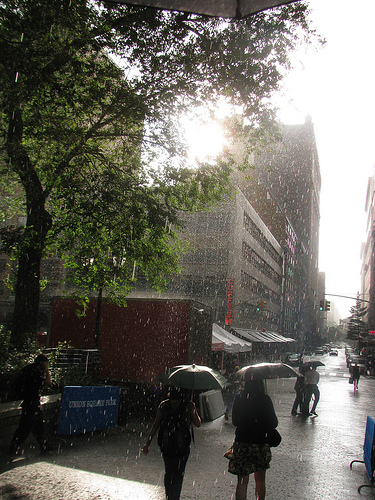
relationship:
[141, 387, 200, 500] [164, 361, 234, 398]
person has umbrella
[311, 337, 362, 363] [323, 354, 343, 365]
parked cars on street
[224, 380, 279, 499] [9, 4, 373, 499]
people walking in rain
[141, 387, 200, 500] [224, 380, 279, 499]
person walking in people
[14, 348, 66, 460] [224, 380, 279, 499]
person walking in people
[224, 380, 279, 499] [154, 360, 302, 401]
people holding umbrellas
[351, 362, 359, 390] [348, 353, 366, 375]
person walking near cars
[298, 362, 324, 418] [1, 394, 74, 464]
man walks along wall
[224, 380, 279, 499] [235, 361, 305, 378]
people carrying an umbrella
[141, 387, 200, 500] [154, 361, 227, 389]
person carrying an umbrella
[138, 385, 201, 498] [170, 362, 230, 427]
person carrying an umbrella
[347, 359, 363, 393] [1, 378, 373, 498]
person walking on sidewalk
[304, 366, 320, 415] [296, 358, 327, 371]
man walking under an umbrella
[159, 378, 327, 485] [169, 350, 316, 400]
people are holding umbrellas